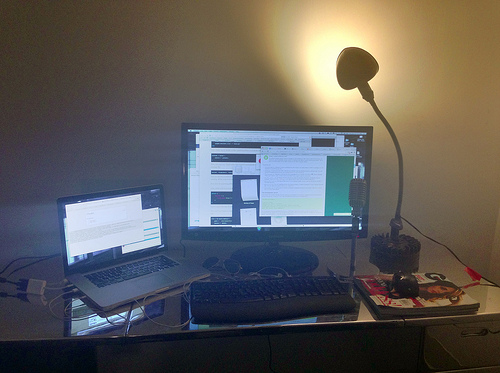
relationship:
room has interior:
[1, 0, 498, 365] [2, 0, 497, 368]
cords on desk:
[0, 277, 104, 321] [0, 240, 498, 342]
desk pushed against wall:
[459, 284, 498, 315] [2, 4, 482, 370]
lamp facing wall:
[337, 46, 420, 257] [5, 5, 495, 262]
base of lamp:
[365, 231, 422, 273] [324, 40, 424, 282]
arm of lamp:
[362, 90, 412, 229] [324, 40, 424, 282]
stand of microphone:
[346, 210, 360, 281] [346, 177, 371, 206]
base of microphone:
[332, 271, 374, 298] [346, 177, 371, 206]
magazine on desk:
[354, 269, 482, 319] [1, 227, 498, 371]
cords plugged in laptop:
[48, 280, 89, 315] [50, 185, 180, 301]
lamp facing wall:
[337, 46, 416, 268] [98, 7, 481, 44]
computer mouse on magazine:
[392, 272, 419, 297] [353, 273, 479, 319]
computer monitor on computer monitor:
[179, 122, 373, 241] [179, 122, 373, 241]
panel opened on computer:
[60, 183, 165, 261] [56, 183, 211, 311]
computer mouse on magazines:
[392, 272, 419, 297] [362, 270, 472, 309]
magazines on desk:
[358, 267, 455, 322] [17, 246, 498, 339]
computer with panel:
[56, 183, 211, 311] [63, 188, 165, 271]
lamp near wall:
[337, 46, 416, 268] [18, 12, 485, 237]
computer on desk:
[56, 183, 211, 311] [1, 244, 491, 371]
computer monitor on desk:
[180, 120, 375, 242] [0, 256, 499, 371]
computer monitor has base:
[179, 122, 373, 241] [225, 245, 324, 274]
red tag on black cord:
[459, 265, 484, 284] [397, 217, 499, 286]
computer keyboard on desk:
[187, 264, 353, 327] [5, 202, 498, 357]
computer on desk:
[56, 183, 211, 311] [8, 255, 498, 359]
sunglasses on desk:
[201, 245, 248, 274] [102, 185, 499, 362]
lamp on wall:
[337, 46, 420, 257] [5, 5, 495, 262]